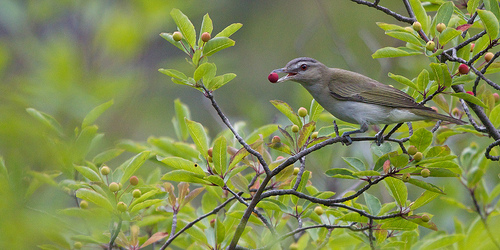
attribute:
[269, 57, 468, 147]
bird — small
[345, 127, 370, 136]
leg — brown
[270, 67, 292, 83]
beak — brown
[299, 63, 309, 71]
eye — brown, black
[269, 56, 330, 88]
head — brown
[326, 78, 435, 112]
wing — brown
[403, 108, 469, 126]
tail — brown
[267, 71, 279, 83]
berry — red, small, round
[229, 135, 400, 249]
branch — brown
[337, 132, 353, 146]
foot — white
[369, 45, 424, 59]
leaf — green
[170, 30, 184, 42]
berry — yellow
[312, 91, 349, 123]
breast — white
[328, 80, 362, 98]
feather — grey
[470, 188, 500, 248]
branch — blurry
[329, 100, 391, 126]
belly — white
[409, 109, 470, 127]
tail feather — long